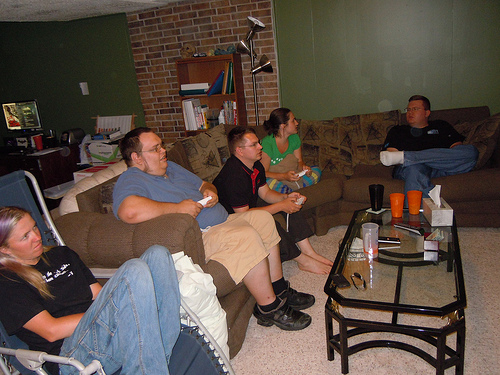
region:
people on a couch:
[110, 90, 451, 248]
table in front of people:
[273, 167, 481, 353]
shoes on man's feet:
[241, 259, 322, 343]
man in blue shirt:
[103, 128, 260, 260]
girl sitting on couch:
[253, 99, 330, 190]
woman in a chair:
[1, 160, 208, 362]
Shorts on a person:
[193, 202, 286, 290]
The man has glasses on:
[111, 120, 176, 190]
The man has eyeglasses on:
[113, 128, 173, 183]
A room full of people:
[5, 66, 497, 366]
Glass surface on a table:
[393, 263, 442, 303]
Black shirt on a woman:
[8, 251, 105, 344]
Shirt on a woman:
[0, 248, 106, 348]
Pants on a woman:
[67, 250, 194, 374]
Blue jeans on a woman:
[60, 244, 197, 374]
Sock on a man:
[376, 143, 407, 173]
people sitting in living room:
[1, 92, 480, 374]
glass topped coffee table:
[323, 201, 468, 373]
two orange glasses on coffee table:
[386, 188, 421, 218]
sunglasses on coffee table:
[346, 271, 368, 293]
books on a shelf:
[183, 96, 245, 128]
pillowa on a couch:
[303, 107, 403, 179]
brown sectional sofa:
[48, 107, 496, 359]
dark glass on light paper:
[362, 180, 382, 211]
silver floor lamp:
[231, 15, 271, 125]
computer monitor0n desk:
[2, 97, 43, 130]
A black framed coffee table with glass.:
[322, 204, 468, 374]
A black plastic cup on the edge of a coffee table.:
[368, 183, 385, 213]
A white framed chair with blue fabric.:
[2, 169, 234, 373]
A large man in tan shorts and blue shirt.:
[110, 127, 315, 330]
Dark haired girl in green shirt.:
[255, 107, 322, 192]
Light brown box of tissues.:
[423, 183, 452, 226]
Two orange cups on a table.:
[389, 191, 421, 217]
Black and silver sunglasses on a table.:
[348, 271, 368, 293]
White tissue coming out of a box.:
[427, 183, 439, 208]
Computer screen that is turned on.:
[1, 97, 43, 135]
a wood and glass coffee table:
[325, 203, 465, 371]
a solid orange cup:
[388, 192, 402, 217]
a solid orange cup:
[405, 188, 422, 213]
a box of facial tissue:
[422, 184, 452, 228]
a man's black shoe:
[252, 302, 311, 329]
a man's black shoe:
[280, 288, 315, 310]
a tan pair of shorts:
[201, 209, 281, 284]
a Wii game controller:
[195, 196, 211, 204]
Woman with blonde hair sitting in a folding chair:
[1, 201, 191, 373]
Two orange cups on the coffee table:
[388, 187, 423, 218]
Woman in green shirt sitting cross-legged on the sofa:
[260, 101, 319, 191]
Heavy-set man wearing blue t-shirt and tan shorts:
[109, 128, 314, 329]